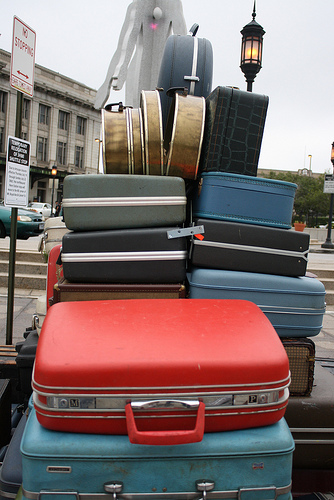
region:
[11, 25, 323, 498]
stacks of suitcases and luggage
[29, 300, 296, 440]
red suitcase with silver accents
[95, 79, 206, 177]
round gold pieces of luggage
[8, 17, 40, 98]
white sign with red lettering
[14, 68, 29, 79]
red arrow on white sign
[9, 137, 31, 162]
white lettering on black background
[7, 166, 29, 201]
black lettering on white background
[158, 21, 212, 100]
black suitcase on top of pile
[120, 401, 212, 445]
red handle of red suitcase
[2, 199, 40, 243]
green car driving down the street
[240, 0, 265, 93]
a black outdoor lamp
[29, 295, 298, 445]
a large red suitcase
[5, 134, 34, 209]
a black and white sign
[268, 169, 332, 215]
a large green tree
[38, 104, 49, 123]
a window of a building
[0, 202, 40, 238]
part of a green car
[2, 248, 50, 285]
part of an outdoor staircase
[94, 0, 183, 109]
part of a large gray statue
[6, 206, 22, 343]
a long black pole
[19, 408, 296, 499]
part of a blue suitcase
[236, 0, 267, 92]
black lamp post behind suitcases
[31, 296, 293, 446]
red suitcase with silver edges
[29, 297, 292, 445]
red suitcase on top of blue suitcase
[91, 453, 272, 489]
brown scruff marks on blue suitcase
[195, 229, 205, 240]
orange sticker on black suitcase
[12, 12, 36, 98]
white sign with red letters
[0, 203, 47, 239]
greenish car past steps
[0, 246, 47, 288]
three steps on left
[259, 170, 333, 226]
green trees in right background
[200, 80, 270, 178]
black alligator print suitcase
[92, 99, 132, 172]
ROUND PIECE OF LUGGAGE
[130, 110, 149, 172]
ROUND PIECE OF LUGGAGE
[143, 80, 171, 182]
ROUND PIECE OF LUGGAGE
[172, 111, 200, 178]
ROUND PIECE OF LUGGAGE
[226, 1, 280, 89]
ILLUMINATED STREET LAMP ON RIGHT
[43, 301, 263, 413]
RED SUIT CASE IN FOREGROUND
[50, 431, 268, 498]
BLUE SUIT CASE IN FOREGROUND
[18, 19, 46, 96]
NO STOPPING SIGN ON LEFT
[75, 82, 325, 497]
LARGE STACK OF SUITCASES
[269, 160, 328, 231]
TREES ON RIGHT IN BACKGROUND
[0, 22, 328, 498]
a large pile of suitcases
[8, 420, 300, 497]
a large light blue suitcase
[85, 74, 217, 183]
three round gold suitcases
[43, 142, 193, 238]
a large light gray suitcase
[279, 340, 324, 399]
a tan checkered suitcase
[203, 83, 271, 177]
an black alegator suitcase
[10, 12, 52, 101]
a white and red sign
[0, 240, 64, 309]
steps behind the suitcases